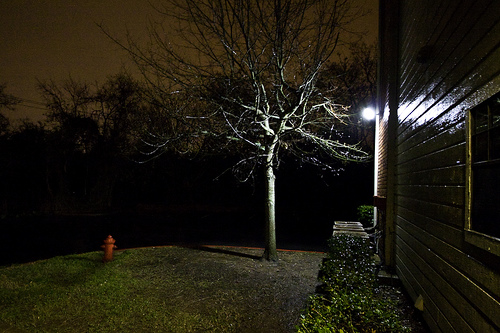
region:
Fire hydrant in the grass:
[98, 233, 115, 266]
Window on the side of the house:
[465, 92, 498, 262]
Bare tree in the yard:
[108, 7, 367, 264]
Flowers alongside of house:
[296, 231, 415, 331]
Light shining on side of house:
[358, 103, 380, 128]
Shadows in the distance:
[0, 121, 379, 267]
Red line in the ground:
[116, 231, 336, 253]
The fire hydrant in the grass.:
[102, 234, 117, 264]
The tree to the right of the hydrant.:
[106, 2, 354, 264]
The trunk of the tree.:
[257, 161, 279, 261]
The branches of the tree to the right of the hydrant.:
[101, 3, 358, 174]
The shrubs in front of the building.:
[304, 232, 418, 332]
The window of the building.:
[467, 102, 499, 249]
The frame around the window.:
[457, 82, 499, 251]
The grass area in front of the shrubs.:
[2, 228, 314, 331]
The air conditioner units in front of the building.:
[333, 217, 366, 245]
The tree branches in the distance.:
[8, 52, 378, 218]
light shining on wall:
[378, 95, 436, 135]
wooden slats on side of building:
[393, 178, 453, 230]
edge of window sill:
[456, 215, 478, 245]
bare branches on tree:
[219, 74, 339, 179]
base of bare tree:
[251, 243, 286, 264]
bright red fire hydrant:
[88, 224, 122, 271]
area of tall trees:
[49, 94, 188, 210]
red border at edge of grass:
[169, 230, 239, 259]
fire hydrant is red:
[102, 234, 116, 263]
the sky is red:
[1, 0, 379, 165]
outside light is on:
[360, 104, 377, 121]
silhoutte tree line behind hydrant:
[1, 45, 379, 267]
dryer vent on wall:
[412, 295, 423, 310]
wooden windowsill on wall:
[460, 81, 499, 261]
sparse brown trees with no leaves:
[93, 3, 374, 264]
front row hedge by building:
[292, 233, 410, 330]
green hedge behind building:
[358, 203, 375, 224]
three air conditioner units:
[328, 219, 370, 246]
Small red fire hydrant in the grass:
[94, 220, 115, 274]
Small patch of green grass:
[8, 295, 36, 323]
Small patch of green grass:
[60, 305, 91, 331]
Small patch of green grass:
[108, 298, 129, 328]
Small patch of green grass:
[181, 255, 239, 303]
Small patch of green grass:
[58, 248, 92, 274]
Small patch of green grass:
[25, 252, 62, 297]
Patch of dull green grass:
[174, 307, 221, 332]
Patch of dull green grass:
[210, 277, 246, 319]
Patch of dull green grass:
[186, 239, 221, 295]